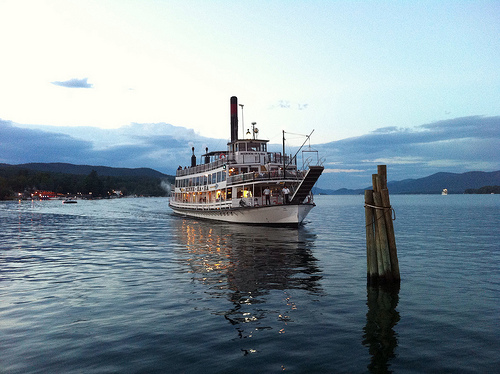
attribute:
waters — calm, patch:
[14, 206, 90, 302]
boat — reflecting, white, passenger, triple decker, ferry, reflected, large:
[131, 124, 323, 227]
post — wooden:
[337, 176, 410, 278]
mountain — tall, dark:
[64, 161, 135, 178]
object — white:
[434, 184, 467, 198]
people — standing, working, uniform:
[229, 178, 295, 206]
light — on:
[287, 208, 300, 220]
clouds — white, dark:
[59, 78, 94, 88]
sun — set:
[58, 99, 125, 122]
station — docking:
[57, 199, 88, 204]